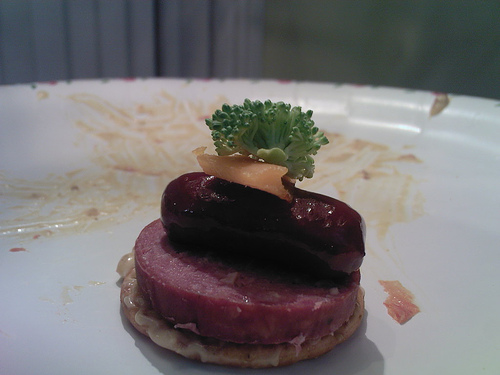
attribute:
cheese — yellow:
[190, 144, 292, 202]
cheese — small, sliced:
[194, 149, 293, 201]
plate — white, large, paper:
[2, 75, 499, 371]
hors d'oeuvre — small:
[116, 94, 374, 374]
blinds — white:
[3, 0, 267, 100]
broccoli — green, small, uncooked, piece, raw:
[202, 97, 331, 184]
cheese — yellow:
[191, 140, 299, 204]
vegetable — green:
[200, 99, 329, 179]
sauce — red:
[375, 277, 417, 325]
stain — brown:
[0, 90, 427, 236]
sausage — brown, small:
[162, 166, 366, 292]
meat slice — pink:
[132, 217, 362, 352]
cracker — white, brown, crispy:
[118, 252, 366, 367]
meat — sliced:
[130, 212, 363, 350]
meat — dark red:
[159, 168, 371, 292]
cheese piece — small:
[195, 143, 296, 198]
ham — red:
[158, 171, 365, 278]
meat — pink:
[135, 217, 362, 341]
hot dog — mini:
[158, 169, 364, 278]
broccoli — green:
[203, 86, 327, 187]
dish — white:
[7, 77, 494, 373]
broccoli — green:
[194, 92, 334, 170]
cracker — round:
[110, 254, 384, 374]